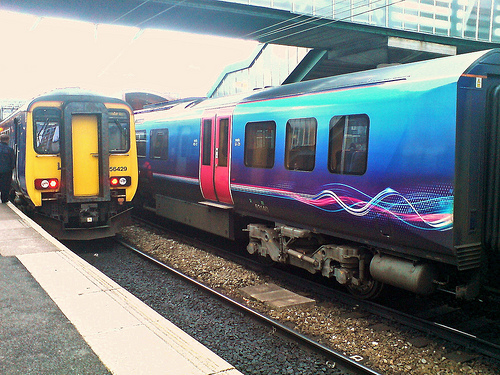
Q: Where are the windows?
A: On the side of a train.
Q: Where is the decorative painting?
A: On the side of a train.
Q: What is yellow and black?
A: Front of a train.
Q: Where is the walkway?
A: Over two trains.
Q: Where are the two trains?
A: Passing at a station.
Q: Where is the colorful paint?
A: Side of train.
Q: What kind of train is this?
A: This is a dark blue train.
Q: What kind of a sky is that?
A: A light white sky.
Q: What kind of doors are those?
A: Pink doors.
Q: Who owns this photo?
A: Zander Zane.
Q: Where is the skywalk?
A: Above the trains.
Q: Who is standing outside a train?
A: A man.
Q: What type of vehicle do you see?
A: Train.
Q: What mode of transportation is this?
A: Train.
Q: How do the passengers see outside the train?
A: Windows.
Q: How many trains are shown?
A: 2.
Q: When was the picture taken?
A: Daytime.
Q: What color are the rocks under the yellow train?
A: Black.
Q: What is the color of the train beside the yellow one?
A: Blue.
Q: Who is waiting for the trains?
A: No One is present.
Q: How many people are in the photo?
A: None.